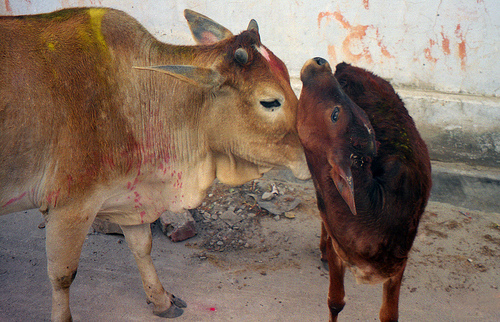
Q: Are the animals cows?
A: Yes, all the animals are cows.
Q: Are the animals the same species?
A: Yes, all the animals are cows.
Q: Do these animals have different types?
A: No, all the animals are cows.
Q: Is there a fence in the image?
A: No, there are no fences.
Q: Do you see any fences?
A: No, there are no fences.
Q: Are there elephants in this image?
A: No, there are no elephants.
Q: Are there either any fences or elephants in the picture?
A: No, there are no elephants or fences.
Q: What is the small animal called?
A: The animal is a calf.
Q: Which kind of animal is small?
A: The animal is a calf.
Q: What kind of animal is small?
A: The animal is a calf.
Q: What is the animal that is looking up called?
A: The animal is a calf.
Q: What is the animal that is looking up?
A: The animal is a calf.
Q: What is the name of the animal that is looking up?
A: The animal is a calf.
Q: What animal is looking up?
A: The animal is a calf.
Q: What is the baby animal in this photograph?
A: The animal is a calf.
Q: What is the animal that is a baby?
A: The animal is a calf.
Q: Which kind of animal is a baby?
A: The animal is a calf.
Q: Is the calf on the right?
A: Yes, the calf is on the right of the image.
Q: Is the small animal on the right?
A: Yes, the calf is on the right of the image.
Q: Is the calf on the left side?
A: No, the calf is on the right of the image.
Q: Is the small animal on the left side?
A: No, the calf is on the right of the image.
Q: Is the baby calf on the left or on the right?
A: The calf is on the right of the image.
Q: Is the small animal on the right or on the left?
A: The calf is on the right of the image.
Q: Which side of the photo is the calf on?
A: The calf is on the right of the image.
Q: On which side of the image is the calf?
A: The calf is on the right of the image.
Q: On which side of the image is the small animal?
A: The calf is on the right of the image.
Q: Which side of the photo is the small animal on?
A: The calf is on the right of the image.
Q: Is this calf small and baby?
A: Yes, the calf is small and baby.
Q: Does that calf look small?
A: Yes, the calf is small.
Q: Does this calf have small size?
A: Yes, the calf is small.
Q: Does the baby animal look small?
A: Yes, the calf is small.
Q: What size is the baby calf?
A: The calf is small.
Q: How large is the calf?
A: The calf is small.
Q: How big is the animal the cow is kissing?
A: The calf is small.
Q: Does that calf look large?
A: No, the calf is small.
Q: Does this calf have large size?
A: No, the calf is small.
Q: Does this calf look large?
A: No, the calf is small.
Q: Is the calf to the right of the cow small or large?
A: The calf is small.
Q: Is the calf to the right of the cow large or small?
A: The calf is small.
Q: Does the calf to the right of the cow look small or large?
A: The calf is small.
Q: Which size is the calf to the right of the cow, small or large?
A: The calf is small.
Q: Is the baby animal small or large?
A: The calf is small.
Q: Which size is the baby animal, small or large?
A: The calf is small.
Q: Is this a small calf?
A: Yes, this is a small calf.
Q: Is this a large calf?
A: No, this is a small calf.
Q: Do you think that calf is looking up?
A: Yes, the calf is looking up.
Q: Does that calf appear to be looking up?
A: Yes, the calf is looking up.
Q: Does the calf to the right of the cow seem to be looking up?
A: Yes, the calf is looking up.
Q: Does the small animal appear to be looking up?
A: Yes, the calf is looking up.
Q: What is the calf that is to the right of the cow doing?
A: The calf is looking up.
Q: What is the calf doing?
A: The calf is looking up.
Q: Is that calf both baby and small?
A: Yes, the calf is a baby and small.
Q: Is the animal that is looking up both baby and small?
A: Yes, the calf is a baby and small.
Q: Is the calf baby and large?
A: No, the calf is a baby but small.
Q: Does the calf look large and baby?
A: No, the calf is a baby but small.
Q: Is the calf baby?
A: Yes, the calf is a baby.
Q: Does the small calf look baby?
A: Yes, the calf is a baby.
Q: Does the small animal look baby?
A: Yes, the calf is a baby.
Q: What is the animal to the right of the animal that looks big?
A: The animal is a calf.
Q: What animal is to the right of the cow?
A: The animal is a calf.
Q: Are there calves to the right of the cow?
A: Yes, there is a calf to the right of the cow.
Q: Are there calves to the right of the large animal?
A: Yes, there is a calf to the right of the cow.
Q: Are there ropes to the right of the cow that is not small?
A: No, there is a calf to the right of the cow.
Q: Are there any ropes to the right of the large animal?
A: No, there is a calf to the right of the cow.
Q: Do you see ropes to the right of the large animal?
A: No, there is a calf to the right of the cow.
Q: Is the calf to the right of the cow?
A: Yes, the calf is to the right of the cow.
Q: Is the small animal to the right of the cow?
A: Yes, the calf is to the right of the cow.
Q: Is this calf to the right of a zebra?
A: No, the calf is to the right of the cow.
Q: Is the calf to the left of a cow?
A: No, the calf is to the right of a cow.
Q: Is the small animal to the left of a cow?
A: No, the calf is to the right of a cow.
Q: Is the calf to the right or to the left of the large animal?
A: The calf is to the right of the cow.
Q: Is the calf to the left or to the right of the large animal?
A: The calf is to the right of the cow.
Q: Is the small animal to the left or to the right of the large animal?
A: The calf is to the right of the cow.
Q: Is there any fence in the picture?
A: No, there are no fences.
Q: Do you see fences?
A: No, there are no fences.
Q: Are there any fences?
A: No, there are no fences.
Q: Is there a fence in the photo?
A: No, there are no fences.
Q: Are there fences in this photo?
A: No, there are no fences.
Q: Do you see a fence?
A: No, there are no fences.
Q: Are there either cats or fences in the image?
A: No, there are no fences or cats.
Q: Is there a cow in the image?
A: Yes, there is a cow.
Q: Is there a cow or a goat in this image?
A: Yes, there is a cow.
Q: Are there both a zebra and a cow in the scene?
A: No, there is a cow but no zebras.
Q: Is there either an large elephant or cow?
A: Yes, there is a large cow.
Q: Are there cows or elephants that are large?
A: Yes, the cow is large.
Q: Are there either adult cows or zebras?
A: Yes, there is an adult cow.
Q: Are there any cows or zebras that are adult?
A: Yes, the cow is adult.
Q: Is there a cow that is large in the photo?
A: Yes, there is a large cow.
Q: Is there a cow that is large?
A: Yes, there is a cow that is large.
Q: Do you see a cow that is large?
A: Yes, there is a cow that is large.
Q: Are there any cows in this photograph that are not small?
A: Yes, there is a large cow.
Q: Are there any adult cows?
A: Yes, there is an adult cow.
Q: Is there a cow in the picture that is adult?
A: Yes, there is a cow that is adult.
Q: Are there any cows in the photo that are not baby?
A: Yes, there is a adult cow.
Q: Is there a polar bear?
A: No, there are no polar bears.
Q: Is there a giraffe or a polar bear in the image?
A: No, there are no polar bears or giraffes.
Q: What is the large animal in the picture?
A: The animal is a cow.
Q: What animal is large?
A: The animal is a cow.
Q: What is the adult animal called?
A: The animal is a cow.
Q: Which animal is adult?
A: The animal is a cow.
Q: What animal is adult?
A: The animal is a cow.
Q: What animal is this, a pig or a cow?
A: This is a cow.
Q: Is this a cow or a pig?
A: This is a cow.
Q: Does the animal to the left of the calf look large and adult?
A: Yes, the cow is large and adult.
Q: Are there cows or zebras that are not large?
A: No, there is a cow but it is large.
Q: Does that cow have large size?
A: Yes, the cow is large.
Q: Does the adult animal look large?
A: Yes, the cow is large.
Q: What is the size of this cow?
A: The cow is large.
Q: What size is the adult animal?
A: The cow is large.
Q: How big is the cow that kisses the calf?
A: The cow is large.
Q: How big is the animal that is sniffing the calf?
A: The cow is large.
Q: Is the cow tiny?
A: No, the cow is large.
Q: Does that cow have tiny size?
A: No, the cow is large.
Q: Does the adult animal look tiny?
A: No, the cow is large.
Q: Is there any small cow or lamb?
A: No, there is a cow but it is large.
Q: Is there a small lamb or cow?
A: No, there is a cow but it is large.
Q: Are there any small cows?
A: No, there is a cow but it is large.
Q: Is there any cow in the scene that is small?
A: No, there is a cow but it is large.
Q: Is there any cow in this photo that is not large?
A: No, there is a cow but it is large.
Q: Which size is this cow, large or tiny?
A: The cow is large.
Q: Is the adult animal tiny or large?
A: The cow is large.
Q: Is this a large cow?
A: Yes, this is a large cow.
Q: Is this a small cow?
A: No, this is a large cow.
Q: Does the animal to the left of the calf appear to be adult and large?
A: Yes, the cow is adult and large.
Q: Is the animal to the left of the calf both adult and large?
A: Yes, the cow is adult and large.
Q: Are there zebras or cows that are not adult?
A: No, there is a cow but it is adult.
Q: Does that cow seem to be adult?
A: Yes, the cow is adult.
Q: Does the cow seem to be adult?
A: Yes, the cow is adult.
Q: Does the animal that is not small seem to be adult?
A: Yes, the cow is adult.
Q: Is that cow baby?
A: No, the cow is adult.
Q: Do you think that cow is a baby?
A: No, the cow is adult.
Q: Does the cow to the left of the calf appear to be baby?
A: No, the cow is adult.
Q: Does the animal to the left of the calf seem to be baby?
A: No, the cow is adult.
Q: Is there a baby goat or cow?
A: No, there is a cow but it is adult.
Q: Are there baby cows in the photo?
A: No, there is a cow but it is adult.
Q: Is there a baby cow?
A: No, there is a cow but it is adult.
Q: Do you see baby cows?
A: No, there is a cow but it is adult.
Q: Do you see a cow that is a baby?
A: No, there is a cow but it is adult.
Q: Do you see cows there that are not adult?
A: No, there is a cow but it is adult.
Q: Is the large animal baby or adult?
A: The cow is adult.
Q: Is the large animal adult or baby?
A: The cow is adult.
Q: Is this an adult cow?
A: Yes, this is an adult cow.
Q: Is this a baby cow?
A: No, this is an adult cow.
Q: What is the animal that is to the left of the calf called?
A: The animal is a cow.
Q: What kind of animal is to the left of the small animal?
A: The animal is a cow.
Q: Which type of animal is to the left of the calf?
A: The animal is a cow.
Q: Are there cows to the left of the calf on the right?
A: Yes, there is a cow to the left of the calf.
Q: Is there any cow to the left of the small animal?
A: Yes, there is a cow to the left of the calf.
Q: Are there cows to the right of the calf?
A: No, the cow is to the left of the calf.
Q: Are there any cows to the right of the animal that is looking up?
A: No, the cow is to the left of the calf.